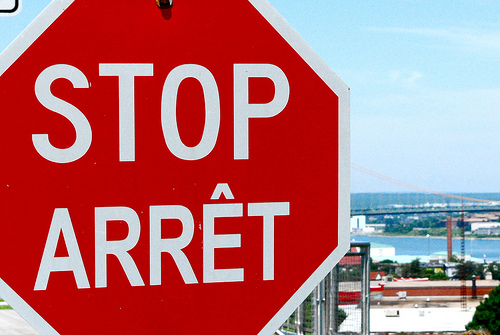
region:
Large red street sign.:
[24, 19, 373, 322]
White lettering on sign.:
[31, 73, 278, 160]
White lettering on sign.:
[84, 235, 295, 299]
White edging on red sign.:
[273, 20, 361, 265]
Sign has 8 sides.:
[9, 20, 391, 294]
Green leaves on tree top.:
[476, 293, 491, 333]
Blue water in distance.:
[396, 237, 446, 253]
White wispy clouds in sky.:
[408, 13, 478, 75]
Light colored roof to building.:
[376, 297, 461, 334]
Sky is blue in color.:
[309, 15, 366, 51]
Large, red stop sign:
[0, 0, 350, 333]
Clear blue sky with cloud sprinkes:
[0, 7, 495, 192]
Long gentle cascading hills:
[345, 187, 495, 203]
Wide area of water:
[350, 231, 495, 261]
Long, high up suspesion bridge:
[350, 145, 495, 255]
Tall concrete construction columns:
[280, 235, 370, 325]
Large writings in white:
[25, 55, 290, 290]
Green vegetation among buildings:
[381, 212, 471, 236]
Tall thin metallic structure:
[455, 187, 470, 313]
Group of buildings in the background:
[446, 200, 499, 235]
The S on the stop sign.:
[25, 55, 98, 165]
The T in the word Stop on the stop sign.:
[91, 58, 154, 164]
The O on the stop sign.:
[157, 52, 222, 167]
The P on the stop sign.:
[230, 60, 292, 161]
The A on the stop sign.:
[35, 196, 81, 291]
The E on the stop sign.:
[190, 195, 245, 285]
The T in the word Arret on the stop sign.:
[246, 195, 293, 283]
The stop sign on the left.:
[3, 3, 350, 334]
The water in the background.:
[377, 228, 496, 263]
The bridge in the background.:
[346, 163, 498, 220]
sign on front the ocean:
[0, 0, 363, 334]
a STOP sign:
[0, 0, 358, 332]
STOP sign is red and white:
[1, 0, 373, 334]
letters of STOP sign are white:
[3, 2, 368, 329]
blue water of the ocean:
[352, 183, 499, 273]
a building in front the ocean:
[346, 199, 398, 279]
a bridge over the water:
[351, 159, 494, 255]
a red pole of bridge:
[429, 189, 459, 257]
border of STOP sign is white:
[2, 0, 353, 332]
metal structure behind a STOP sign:
[248, 148, 378, 333]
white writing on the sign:
[22, 35, 301, 169]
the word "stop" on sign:
[36, 57, 290, 165]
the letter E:
[181, 189, 256, 291]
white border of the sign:
[321, 139, 368, 223]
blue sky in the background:
[363, 25, 459, 83]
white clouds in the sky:
[409, 13, 472, 77]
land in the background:
[393, 191, 491, 244]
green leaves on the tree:
[464, 290, 495, 325]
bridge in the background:
[390, 179, 467, 220]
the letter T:
[236, 178, 314, 273]